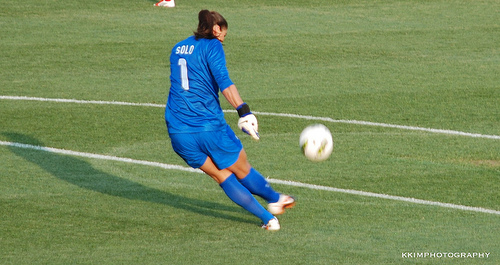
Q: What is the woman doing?
A: Playing soccer.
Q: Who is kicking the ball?
A: The woman.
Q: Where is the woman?
A: On a soccer field.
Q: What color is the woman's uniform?
A: Blue.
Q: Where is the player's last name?
A: On her jersey.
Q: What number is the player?
A: One.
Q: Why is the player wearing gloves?
A: She's a goalie.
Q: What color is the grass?
A: Green.